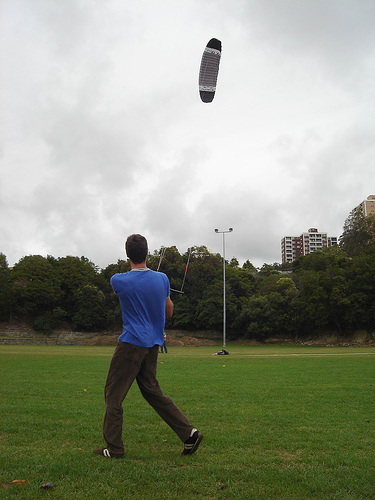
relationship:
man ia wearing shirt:
[95, 233, 204, 460] [108, 267, 172, 350]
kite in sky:
[198, 36, 223, 105] [2, 0, 374, 269]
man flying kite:
[95, 233, 204, 460] [198, 36, 223, 105]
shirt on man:
[108, 267, 172, 350] [95, 233, 204, 460]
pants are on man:
[101, 339, 195, 455] [95, 233, 204, 460]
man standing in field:
[95, 233, 204, 460] [2, 344, 375, 499]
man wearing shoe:
[95, 233, 204, 460] [179, 430, 202, 458]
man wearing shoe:
[95, 233, 204, 460] [92, 447, 126, 460]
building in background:
[280, 227, 339, 269] [1, 171, 374, 285]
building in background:
[356, 193, 374, 229] [1, 171, 374, 285]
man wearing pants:
[95, 233, 204, 460] [101, 339, 195, 455]